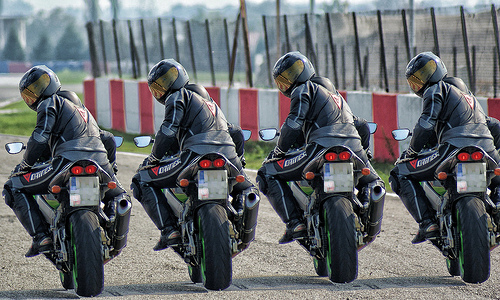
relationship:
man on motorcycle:
[131, 55, 251, 202] [195, 46, 421, 279]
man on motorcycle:
[4, 48, 132, 297] [158, 122, 281, 285]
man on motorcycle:
[382, 46, 499, 248] [384, 126, 499, 295]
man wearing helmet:
[131, 57, 254, 252] [142, 52, 191, 97]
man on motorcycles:
[254, 52, 381, 243] [2, 125, 480, 299]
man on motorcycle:
[131, 57, 254, 252] [390, 124, 499, 287]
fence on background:
[92, 47, 417, 81] [1, 15, 499, 62]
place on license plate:
[195, 168, 230, 201] [193, 169, 229, 201]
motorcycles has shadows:
[2, 125, 480, 299] [3, 271, 479, 298]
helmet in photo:
[144, 64, 187, 102] [1, 4, 486, 298]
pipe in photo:
[357, 176, 388, 210] [1, 4, 486, 298]